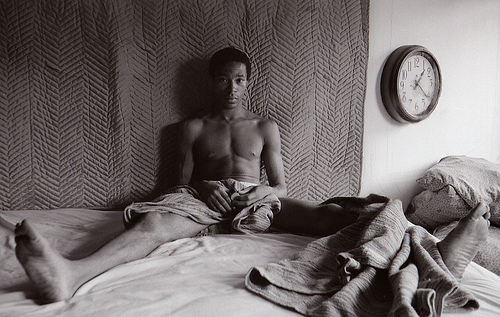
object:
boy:
[13, 45, 363, 305]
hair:
[205, 47, 252, 82]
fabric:
[0, 1, 369, 212]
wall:
[0, 1, 499, 215]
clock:
[378, 45, 441, 128]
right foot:
[15, 215, 72, 305]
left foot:
[435, 201, 492, 280]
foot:
[435, 200, 492, 280]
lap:
[132, 183, 214, 234]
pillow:
[415, 154, 499, 218]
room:
[2, 2, 499, 316]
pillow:
[406, 186, 476, 228]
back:
[0, 1, 369, 212]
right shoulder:
[174, 109, 215, 149]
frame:
[380, 44, 443, 126]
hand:
[411, 68, 426, 91]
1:
[421, 56, 426, 69]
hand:
[413, 79, 430, 100]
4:
[426, 90, 431, 102]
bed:
[3, 208, 498, 316]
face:
[215, 58, 245, 108]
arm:
[264, 141, 288, 200]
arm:
[172, 134, 195, 187]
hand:
[198, 178, 236, 218]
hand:
[230, 184, 273, 210]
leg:
[71, 207, 209, 292]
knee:
[139, 209, 169, 243]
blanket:
[243, 190, 479, 317]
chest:
[198, 126, 262, 169]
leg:
[272, 194, 433, 255]